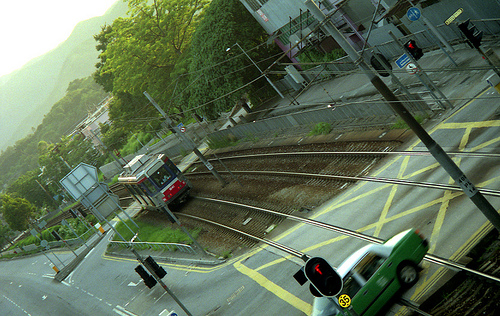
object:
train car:
[117, 154, 192, 213]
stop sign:
[303, 256, 343, 297]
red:
[315, 264, 321, 273]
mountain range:
[0, 0, 130, 147]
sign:
[337, 294, 352, 308]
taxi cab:
[308, 229, 432, 315]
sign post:
[126, 250, 192, 316]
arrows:
[8, 281, 15, 285]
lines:
[311, 163, 440, 212]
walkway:
[232, 89, 499, 316]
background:
[0, 0, 500, 315]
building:
[76, 91, 128, 156]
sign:
[136, 255, 168, 287]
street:
[203, 47, 500, 130]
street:
[0, 251, 305, 314]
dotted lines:
[69, 278, 113, 307]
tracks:
[170, 196, 499, 315]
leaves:
[122, 19, 146, 34]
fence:
[207, 91, 425, 144]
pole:
[417, 19, 462, 68]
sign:
[404, 6, 421, 22]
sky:
[0, 1, 126, 78]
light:
[407, 39, 413, 48]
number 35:
[338, 295, 352, 305]